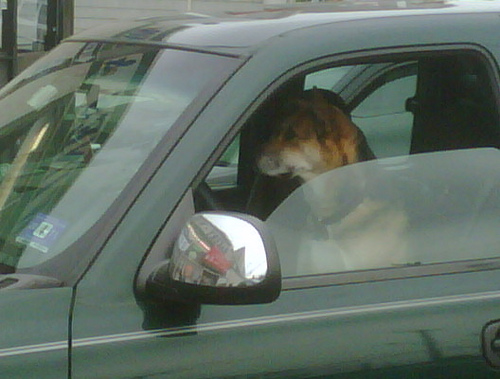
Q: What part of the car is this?
A: Left door on green car.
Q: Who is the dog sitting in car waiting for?
A: The pet owner.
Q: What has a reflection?
A: Side view mirror.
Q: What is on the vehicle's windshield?
A: Reflections.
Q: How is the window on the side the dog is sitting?
A: Partially open.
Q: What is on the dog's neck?
A: A collar.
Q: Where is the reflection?
A: In a chromed sideview mirror.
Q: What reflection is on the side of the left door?
A: Power lines.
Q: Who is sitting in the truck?
A: A dog.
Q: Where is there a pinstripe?
A: Side of truck.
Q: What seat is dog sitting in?
A: Left seat.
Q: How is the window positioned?
A: Opened halfway.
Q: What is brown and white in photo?
A: Dog.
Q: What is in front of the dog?
A: Steering wheel.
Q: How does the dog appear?
A: Content.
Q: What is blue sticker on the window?
A: Registration.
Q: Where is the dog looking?
A: Out window.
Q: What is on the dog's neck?
A: Collar.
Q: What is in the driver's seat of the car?
A: Dog.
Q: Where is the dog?
A: In the car.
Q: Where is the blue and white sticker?
A: On the windshield.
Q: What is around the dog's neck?
A: Collar.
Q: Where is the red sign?
A: In the reflection on the mirror.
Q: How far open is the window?
A: Half way.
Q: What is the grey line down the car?
A: Pinstripe.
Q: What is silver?
A: The back of the side mirror.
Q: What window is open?
A: Driver's door.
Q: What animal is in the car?
A: A dog.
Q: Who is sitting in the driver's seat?
A: A dog.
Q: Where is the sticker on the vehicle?
A: On the windshield.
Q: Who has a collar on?
A: The dog.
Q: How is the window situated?
A: It's half-open.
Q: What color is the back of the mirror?
A: Silver.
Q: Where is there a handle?
A: On the door.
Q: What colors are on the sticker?
A: Blue and white.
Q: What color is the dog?
A: Brown.